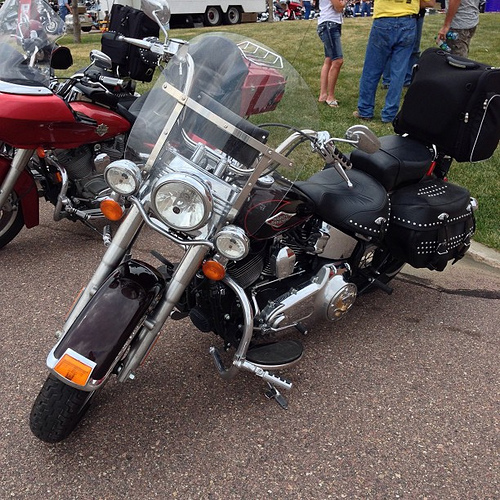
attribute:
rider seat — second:
[348, 132, 460, 181]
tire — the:
[27, 374, 92, 444]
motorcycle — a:
[27, 32, 480, 446]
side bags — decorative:
[383, 176, 479, 271]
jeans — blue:
[352, 13, 417, 124]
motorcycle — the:
[26, 5, 499, 447]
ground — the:
[0, 12, 492, 494]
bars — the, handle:
[118, 31, 359, 165]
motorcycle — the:
[84, 136, 371, 320]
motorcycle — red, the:
[5, 69, 158, 246]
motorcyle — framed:
[6, 53, 143, 256]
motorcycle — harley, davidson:
[67, 19, 477, 377]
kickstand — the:
[206, 358, 305, 398]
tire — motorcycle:
[27, 259, 167, 445]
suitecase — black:
[392, 39, 498, 179]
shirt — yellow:
[366, 0, 424, 23]